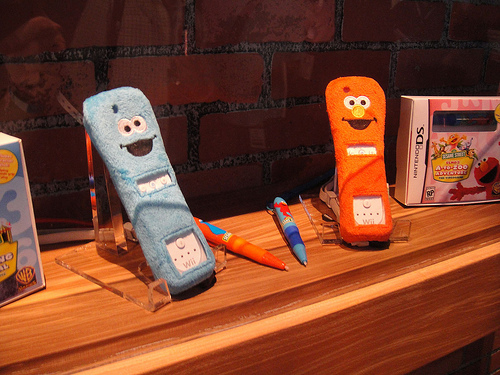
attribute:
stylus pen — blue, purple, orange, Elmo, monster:
[271, 194, 308, 269]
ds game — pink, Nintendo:
[394, 93, 499, 205]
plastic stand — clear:
[55, 128, 227, 315]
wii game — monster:
[325, 75, 393, 241]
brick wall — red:
[2, 1, 498, 223]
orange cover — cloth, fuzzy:
[324, 73, 393, 242]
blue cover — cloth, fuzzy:
[81, 85, 216, 295]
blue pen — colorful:
[265, 196, 307, 267]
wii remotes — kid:
[82, 76, 394, 295]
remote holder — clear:
[298, 149, 411, 244]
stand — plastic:
[59, 123, 227, 312]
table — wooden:
[0, 185, 498, 370]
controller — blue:
[85, 85, 215, 296]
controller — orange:
[325, 74, 394, 249]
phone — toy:
[297, 76, 415, 260]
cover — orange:
[308, 89, 380, 234]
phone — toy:
[81, 122, 238, 297]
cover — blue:
[108, 137, 198, 284]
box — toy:
[0, 132, 52, 299]